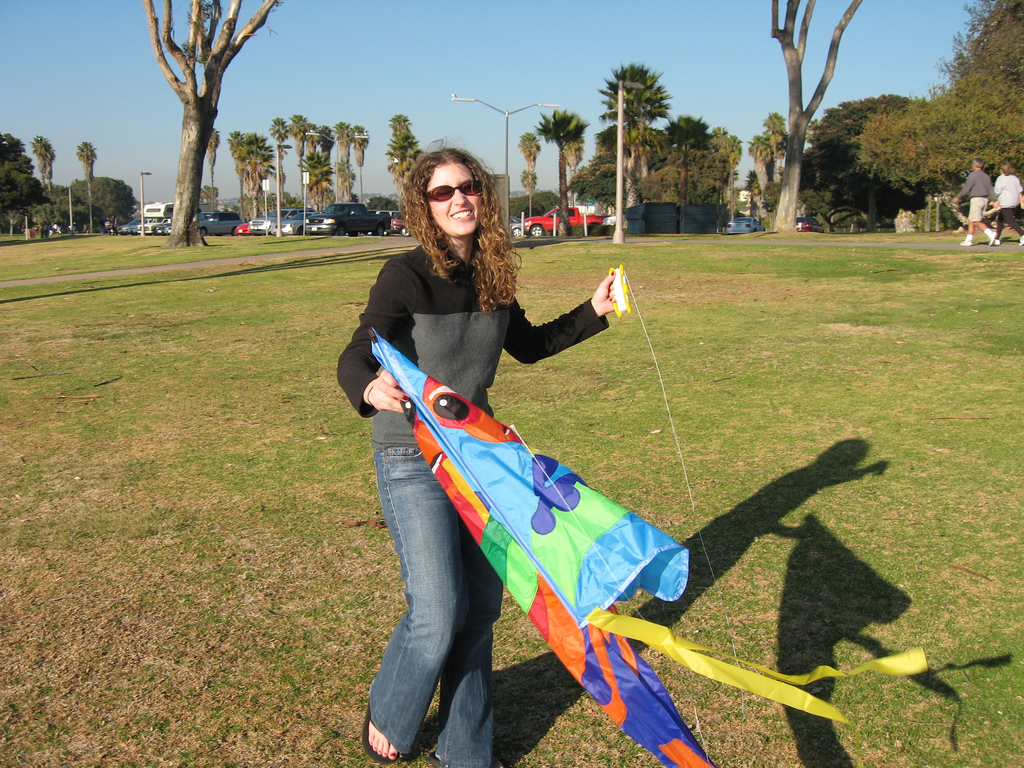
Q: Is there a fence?
A: No, there are no fences.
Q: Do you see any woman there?
A: Yes, there is a woman.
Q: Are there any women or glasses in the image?
A: Yes, there is a woman.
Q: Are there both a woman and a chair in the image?
A: No, there is a woman but no chairs.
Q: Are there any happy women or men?
A: Yes, there is a happy woman.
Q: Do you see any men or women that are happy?
A: Yes, the woman is happy.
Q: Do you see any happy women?
A: Yes, there is a happy woman.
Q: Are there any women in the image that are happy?
A: Yes, there is a happy woman.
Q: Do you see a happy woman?
A: Yes, there is a happy woman.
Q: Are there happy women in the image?
A: Yes, there is a happy woman.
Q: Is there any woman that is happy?
A: Yes, there is a woman that is happy.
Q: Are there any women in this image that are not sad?
A: Yes, there is a happy woman.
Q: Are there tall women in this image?
A: Yes, there is a tall woman.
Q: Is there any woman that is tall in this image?
A: Yes, there is a tall woman.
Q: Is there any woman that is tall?
A: Yes, there is a woman that is tall.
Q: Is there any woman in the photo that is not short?
A: Yes, there is a tall woman.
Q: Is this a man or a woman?
A: This is a woman.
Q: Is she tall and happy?
A: Yes, the woman is tall and happy.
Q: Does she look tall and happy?
A: Yes, the woman is tall and happy.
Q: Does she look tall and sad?
A: No, the woman is tall but happy.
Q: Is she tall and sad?
A: No, the woman is tall but happy.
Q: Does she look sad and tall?
A: No, the woman is tall but happy.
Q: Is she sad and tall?
A: No, the woman is tall but happy.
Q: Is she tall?
A: Yes, the woman is tall.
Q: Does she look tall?
A: Yes, the woman is tall.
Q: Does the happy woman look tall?
A: Yes, the woman is tall.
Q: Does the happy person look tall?
A: Yes, the woman is tall.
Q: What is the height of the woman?
A: The woman is tall.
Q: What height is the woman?
A: The woman is tall.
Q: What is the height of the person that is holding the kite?
A: The woman is tall.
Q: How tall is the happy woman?
A: The woman is tall.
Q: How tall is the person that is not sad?
A: The woman is tall.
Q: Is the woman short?
A: No, the woman is tall.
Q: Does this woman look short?
A: No, the woman is tall.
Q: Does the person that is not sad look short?
A: No, the woman is tall.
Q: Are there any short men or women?
A: No, there is a woman but she is tall.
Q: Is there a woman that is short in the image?
A: No, there is a woman but she is tall.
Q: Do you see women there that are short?
A: No, there is a woman but she is tall.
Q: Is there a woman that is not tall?
A: No, there is a woman but she is tall.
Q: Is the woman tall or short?
A: The woman is tall.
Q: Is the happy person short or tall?
A: The woman is tall.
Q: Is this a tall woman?
A: Yes, this is a tall woman.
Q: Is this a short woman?
A: No, this is a tall woman.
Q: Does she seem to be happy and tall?
A: Yes, the woman is happy and tall.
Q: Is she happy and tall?
A: Yes, the woman is happy and tall.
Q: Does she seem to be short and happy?
A: No, the woman is happy but tall.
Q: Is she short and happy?
A: No, the woman is happy but tall.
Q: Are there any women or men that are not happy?
A: No, there is a woman but she is happy.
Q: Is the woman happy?
A: Yes, the woman is happy.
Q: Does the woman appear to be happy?
A: Yes, the woman is happy.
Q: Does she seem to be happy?
A: Yes, the woman is happy.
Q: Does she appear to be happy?
A: Yes, the woman is happy.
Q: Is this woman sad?
A: No, the woman is happy.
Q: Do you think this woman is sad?
A: No, the woman is happy.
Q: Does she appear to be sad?
A: No, the woman is happy.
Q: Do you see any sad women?
A: No, there is a woman but she is happy.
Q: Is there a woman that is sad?
A: No, there is a woman but she is happy.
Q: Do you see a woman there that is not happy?
A: No, there is a woman but she is happy.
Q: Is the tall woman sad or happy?
A: The woman is happy.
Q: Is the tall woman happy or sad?
A: The woman is happy.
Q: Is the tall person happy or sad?
A: The woman is happy.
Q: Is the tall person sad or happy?
A: The woman is happy.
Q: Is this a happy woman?
A: Yes, this is a happy woman.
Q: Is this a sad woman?
A: No, this is a happy woman.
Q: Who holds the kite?
A: The woman holds the kite.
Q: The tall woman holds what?
A: The woman holds the kite.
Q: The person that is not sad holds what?
A: The woman holds the kite.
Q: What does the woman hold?
A: The woman holds the kite.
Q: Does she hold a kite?
A: Yes, the woman holds a kite.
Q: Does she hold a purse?
A: No, the woman holds a kite.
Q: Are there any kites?
A: Yes, there is a kite.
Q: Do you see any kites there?
A: Yes, there is a kite.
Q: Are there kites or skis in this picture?
A: Yes, there is a kite.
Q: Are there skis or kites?
A: Yes, there is a kite.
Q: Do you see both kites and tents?
A: No, there is a kite but no tents.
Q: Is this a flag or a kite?
A: This is a kite.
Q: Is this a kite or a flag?
A: This is a kite.